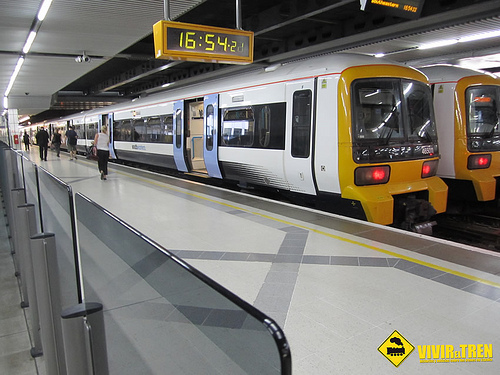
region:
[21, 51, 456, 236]
yellow and silver train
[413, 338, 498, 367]
writing in yellow text at bottom of photo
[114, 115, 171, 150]
windows on side of train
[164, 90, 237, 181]
open train doors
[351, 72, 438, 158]
windshield on front of train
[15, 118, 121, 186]
people walking on train platform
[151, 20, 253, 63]
yellow time clock hanging from a ceiling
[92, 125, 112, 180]
woman walking to her train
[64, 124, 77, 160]
man walking to catch his train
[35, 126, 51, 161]
man walking to catch his train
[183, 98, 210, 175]
open door on a subway train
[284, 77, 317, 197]
white driver door on a subway train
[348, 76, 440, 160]
clear glass window on a train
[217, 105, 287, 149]
black glass window on a subway train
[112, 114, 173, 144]
multiple windows on a subway train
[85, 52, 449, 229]
a white and yellow train passenger car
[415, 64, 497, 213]
a white and yellow train passenger car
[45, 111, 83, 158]
a white train passenger car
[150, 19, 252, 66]
overhead digital time clock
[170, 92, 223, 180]
open blue passenger doors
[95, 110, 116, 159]
open blue passenger doors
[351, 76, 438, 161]
a train front windshield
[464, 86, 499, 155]
a train front windshield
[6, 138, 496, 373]
a passenger boarding platform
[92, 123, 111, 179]
a passenger walking on platform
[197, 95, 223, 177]
Light blue door on a train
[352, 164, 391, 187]
Red light on the back of a train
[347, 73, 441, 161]
Large window on a train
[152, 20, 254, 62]
Yellow sign hanging in a train station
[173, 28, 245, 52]
Yellow numbers on a sign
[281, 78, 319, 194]
White door on a train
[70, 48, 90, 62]
Security camera on the ceiling of a train station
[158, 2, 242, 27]
Poles holding up a sign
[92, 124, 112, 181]
Woman walking near a train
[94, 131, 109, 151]
A sleeveless white shirt on a woman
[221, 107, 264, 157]
a window n a train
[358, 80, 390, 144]
a window n a train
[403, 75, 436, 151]
a window n a train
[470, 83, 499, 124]
a window n a train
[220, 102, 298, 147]
a window n a train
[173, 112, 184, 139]
a window n a train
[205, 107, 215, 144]
a window n a train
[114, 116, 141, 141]
a window n a train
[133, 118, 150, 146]
a window n a train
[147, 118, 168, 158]
a window n a train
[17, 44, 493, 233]
white and yellow trains stopping at station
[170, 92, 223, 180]
open blue doors with oval windows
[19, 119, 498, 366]
people walking down gray and yellow platform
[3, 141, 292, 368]
partition of tinted glass panels and poles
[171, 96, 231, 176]
train open door in the station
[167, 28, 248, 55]
black and yellow clock display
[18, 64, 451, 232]
train near the platform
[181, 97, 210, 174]
open door near the clock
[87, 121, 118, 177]
woman with a white shirt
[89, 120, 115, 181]
person with a white shirt on the platform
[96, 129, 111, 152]
white sleeveless shirt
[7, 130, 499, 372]
tiled sidewalk at a station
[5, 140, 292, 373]
glass rail near a sidewalk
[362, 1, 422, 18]
sign hanging above the trains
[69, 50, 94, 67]
security camera on the ceiling